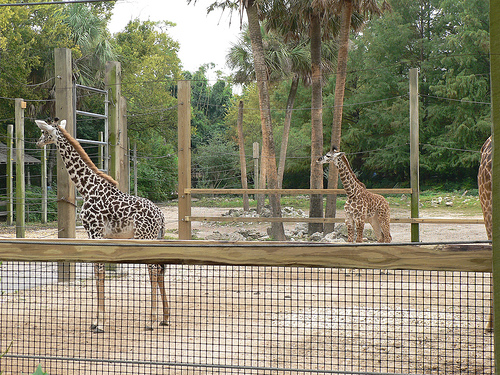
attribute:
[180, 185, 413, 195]
beam — wooden 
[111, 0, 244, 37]
sky — hazy, gray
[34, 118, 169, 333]
giraffe — hooves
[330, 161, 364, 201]
neck — long 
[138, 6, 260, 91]
sky — overcast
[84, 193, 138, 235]
spots — brown , white 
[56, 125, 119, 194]
fur — black, orange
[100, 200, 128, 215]
pattern —  side 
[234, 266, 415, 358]
fencing — black metal 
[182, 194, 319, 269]
rocks — around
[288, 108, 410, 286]
giraffe — legs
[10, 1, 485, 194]
leaves — green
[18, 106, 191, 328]
giraffe — brown, white 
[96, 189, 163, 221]
giraffe —  side 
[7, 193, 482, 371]
field — dirt